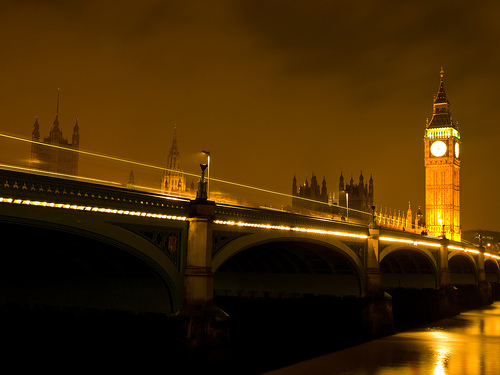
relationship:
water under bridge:
[324, 326, 435, 372] [219, 175, 431, 298]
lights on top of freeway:
[70, 176, 366, 254] [3, 157, 489, 264]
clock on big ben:
[429, 139, 446, 159] [423, 67, 460, 243]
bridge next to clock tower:
[0, 155, 500, 330] [414, 63, 464, 234]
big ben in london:
[416, 60, 464, 248] [1, 2, 497, 372]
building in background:
[291, 171, 372, 222] [8, 9, 494, 242]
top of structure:
[161, 135, 187, 195] [156, 135, 196, 240]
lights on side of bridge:
[46, 189, 111, 213] [71, 187, 441, 367]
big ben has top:
[423, 67, 460, 243] [424, 66, 459, 131]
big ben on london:
[423, 67, 460, 243] [1, 2, 497, 372]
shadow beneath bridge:
[4, 227, 497, 372] [1, 162, 498, 354]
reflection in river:
[378, 302, 498, 372] [7, 294, 497, 371]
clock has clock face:
[430, 140, 447, 156] [430, 140, 447, 157]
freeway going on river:
[0, 164, 499, 253] [370, 302, 498, 374]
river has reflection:
[370, 302, 498, 374] [392, 314, 499, 375]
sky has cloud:
[1, 1, 498, 125] [6, 3, 496, 231]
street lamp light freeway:
[191, 145, 215, 200] [0, 164, 499, 253]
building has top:
[288, 169, 375, 211] [338, 172, 374, 211]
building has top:
[288, 169, 375, 211] [288, 172, 328, 200]